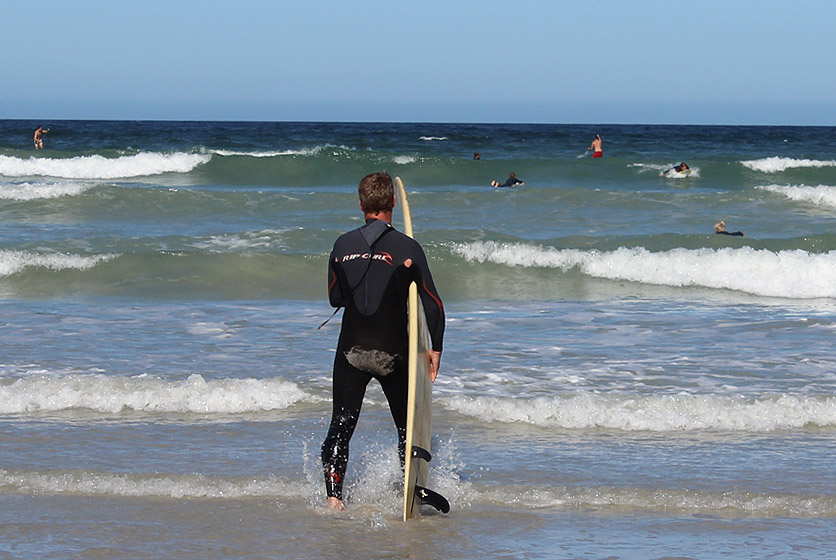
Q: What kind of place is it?
A: It is an ocean.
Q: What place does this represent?
A: It represents the ocean.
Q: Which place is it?
A: It is an ocean.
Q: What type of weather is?
A: It is clear.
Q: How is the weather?
A: It is clear.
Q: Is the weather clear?
A: Yes, it is clear.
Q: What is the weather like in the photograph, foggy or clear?
A: It is clear.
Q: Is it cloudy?
A: No, it is clear.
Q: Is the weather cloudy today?
A: No, it is clear.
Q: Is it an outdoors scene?
A: Yes, it is outdoors.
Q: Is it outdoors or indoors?
A: It is outdoors.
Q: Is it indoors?
A: No, it is outdoors.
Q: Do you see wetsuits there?
A: Yes, there is a wetsuit.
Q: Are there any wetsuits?
A: Yes, there is a wetsuit.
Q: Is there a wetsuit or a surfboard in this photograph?
A: Yes, there is a wetsuit.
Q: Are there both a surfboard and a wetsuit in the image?
A: Yes, there are both a wetsuit and a surfboard.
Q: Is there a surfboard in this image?
A: Yes, there is a surfboard.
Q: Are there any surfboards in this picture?
A: Yes, there is a surfboard.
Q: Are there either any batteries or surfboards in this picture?
A: Yes, there is a surfboard.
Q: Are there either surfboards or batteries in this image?
A: Yes, there is a surfboard.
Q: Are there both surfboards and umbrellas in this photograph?
A: No, there is a surfboard but no umbrellas.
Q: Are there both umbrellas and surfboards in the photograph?
A: No, there is a surfboard but no umbrellas.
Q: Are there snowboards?
A: No, there are no snowboards.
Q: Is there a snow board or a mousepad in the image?
A: No, there are no snowboards or mouse pads.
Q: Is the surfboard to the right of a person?
A: No, the surfboard is to the left of a person.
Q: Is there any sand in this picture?
A: Yes, there is sand.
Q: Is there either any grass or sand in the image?
A: Yes, there is sand.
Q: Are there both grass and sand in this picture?
A: No, there is sand but no grass.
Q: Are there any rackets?
A: No, there are no rackets.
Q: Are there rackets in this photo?
A: No, there are no rackets.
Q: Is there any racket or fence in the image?
A: No, there are no rackets or fences.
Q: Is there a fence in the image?
A: No, there are no fences.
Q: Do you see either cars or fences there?
A: No, there are no fences or cars.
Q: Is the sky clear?
A: Yes, the sky is clear.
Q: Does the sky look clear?
A: Yes, the sky is clear.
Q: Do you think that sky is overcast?
A: No, the sky is clear.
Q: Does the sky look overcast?
A: No, the sky is clear.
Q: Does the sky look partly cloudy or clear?
A: The sky is clear.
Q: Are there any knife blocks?
A: No, there are no knife blocks.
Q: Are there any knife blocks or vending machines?
A: No, there are no knife blocks or vending machines.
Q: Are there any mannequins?
A: No, there are no mannequins.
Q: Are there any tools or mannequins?
A: No, there are no mannequins or tools.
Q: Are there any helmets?
A: No, there are no helmets.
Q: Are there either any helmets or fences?
A: No, there are no helmets or fences.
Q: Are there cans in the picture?
A: No, there are no cans.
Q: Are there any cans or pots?
A: No, there are no cans or pots.